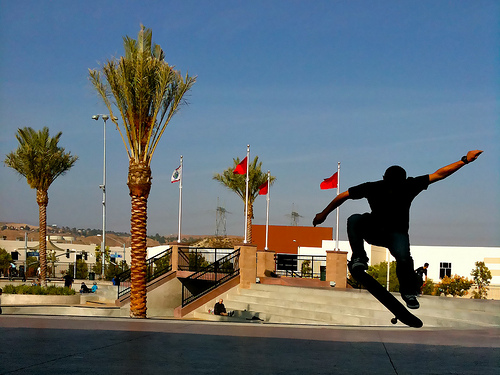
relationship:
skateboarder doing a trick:
[305, 145, 485, 308] [306, 141, 486, 341]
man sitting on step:
[210, 296, 230, 320] [195, 285, 362, 322]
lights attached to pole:
[92, 111, 120, 128] [100, 113, 108, 277]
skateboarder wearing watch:
[305, 145, 485, 308] [458, 155, 470, 166]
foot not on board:
[397, 284, 425, 312] [337, 260, 426, 335]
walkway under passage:
[127, 279, 209, 318] [160, 240, 273, 285]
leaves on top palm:
[83, 20, 195, 159] [86, 17, 198, 317]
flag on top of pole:
[316, 168, 341, 192] [335, 159, 342, 247]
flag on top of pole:
[232, 155, 251, 179] [244, 141, 251, 247]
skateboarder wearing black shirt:
[305, 145, 485, 308] [348, 173, 433, 237]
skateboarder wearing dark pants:
[305, 145, 485, 308] [344, 214, 425, 296]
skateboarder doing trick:
[305, 145, 485, 308] [306, 141, 486, 341]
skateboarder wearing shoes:
[305, 145, 485, 308] [349, 253, 423, 314]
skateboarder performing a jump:
[305, 145, 485, 308] [304, 143, 485, 374]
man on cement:
[210, 296, 230, 320] [199, 313, 238, 323]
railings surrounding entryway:
[273, 251, 328, 281] [235, 238, 351, 291]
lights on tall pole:
[92, 111, 120, 128] [97, 113, 110, 278]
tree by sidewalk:
[86, 17, 198, 317] [4, 311, 377, 328]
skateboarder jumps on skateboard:
[305, 145, 485, 308] [337, 260, 426, 335]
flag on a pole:
[316, 168, 341, 192] [335, 159, 342, 247]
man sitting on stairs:
[210, 296, 230, 320] [198, 275, 498, 331]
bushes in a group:
[5, 283, 76, 299] [3, 280, 81, 295]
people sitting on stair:
[210, 296, 230, 320] [198, 275, 498, 331]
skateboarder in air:
[305, 145, 485, 308] [245, 77, 499, 341]